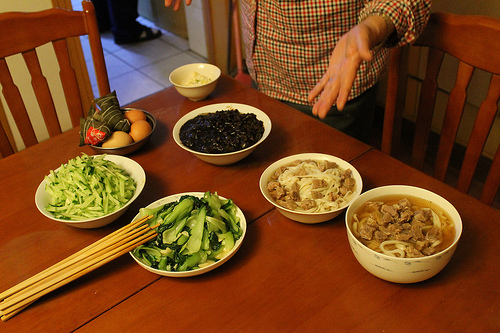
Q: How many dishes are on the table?
A: Seven.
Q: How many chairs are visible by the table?
A: Two.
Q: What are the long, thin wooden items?
A: Chopsticks.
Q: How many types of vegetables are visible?
A: Two.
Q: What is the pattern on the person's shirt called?
A: Plaid.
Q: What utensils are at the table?
A: Chopsticks.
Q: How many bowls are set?
A: Seven.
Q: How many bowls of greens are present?
A: Two.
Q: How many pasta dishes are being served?
A: Two.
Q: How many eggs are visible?
A: Three.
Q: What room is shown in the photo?
A: Dining room.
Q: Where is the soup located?
A: To the far right.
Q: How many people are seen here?
A: Two.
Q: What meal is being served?
A: Dinner.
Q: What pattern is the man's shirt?
A: Plaid.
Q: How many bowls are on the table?
A: Seven.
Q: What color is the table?
A: Brown.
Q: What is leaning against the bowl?
A: Chopsticks.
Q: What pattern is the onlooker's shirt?
A: Checkered.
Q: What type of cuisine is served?
A: Asian.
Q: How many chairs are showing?
A: Two.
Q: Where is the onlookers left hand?
A: Above the table.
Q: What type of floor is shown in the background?
A: Tile.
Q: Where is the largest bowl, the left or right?
A: Right.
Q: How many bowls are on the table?
A: Seven.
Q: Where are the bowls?
A: On the table.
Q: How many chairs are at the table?
A: Two.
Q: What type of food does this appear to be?
A: Oriental.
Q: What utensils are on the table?
A: Chopsticks.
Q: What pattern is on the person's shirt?
A: Plaid.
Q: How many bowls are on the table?
A: Seven.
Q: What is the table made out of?
A: Wood.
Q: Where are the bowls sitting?
A: On the table.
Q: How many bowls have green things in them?
A: Two.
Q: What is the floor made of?
A: Tiles.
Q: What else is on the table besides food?
A: Chopsticks.